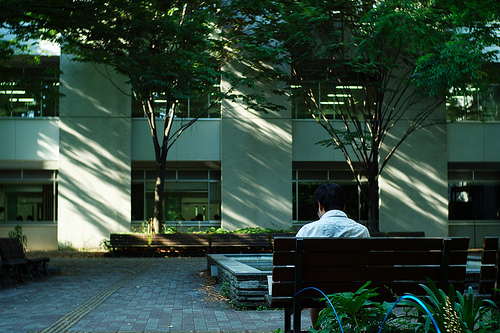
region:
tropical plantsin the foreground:
[314, 282, 498, 332]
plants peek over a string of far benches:
[108, 217, 424, 255]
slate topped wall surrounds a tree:
[203, 244, 267, 307]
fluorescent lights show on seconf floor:
[1, 64, 493, 116]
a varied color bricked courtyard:
[6, 244, 269, 330]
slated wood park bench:
[273, 234, 471, 306]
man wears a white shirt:
[293, 204, 373, 241]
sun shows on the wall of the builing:
[13, 18, 447, 248]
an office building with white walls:
[2, 19, 497, 249]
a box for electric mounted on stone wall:
[198, 255, 227, 284]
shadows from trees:
[55, 48, 129, 188]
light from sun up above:
[44, 151, 134, 210]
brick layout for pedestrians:
[56, 259, 186, 313]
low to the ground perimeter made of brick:
[207, 246, 263, 299]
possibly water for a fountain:
[253, 260, 269, 267]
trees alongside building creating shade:
[59, 6, 238, 227]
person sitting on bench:
[268, 183, 465, 288]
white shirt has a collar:
[298, 210, 373, 237]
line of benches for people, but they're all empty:
[103, 233, 271, 248]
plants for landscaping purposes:
[432, 284, 494, 330]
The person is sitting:
[256, 155, 386, 281]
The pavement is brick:
[102, 278, 182, 328]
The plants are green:
[325, 290, 442, 330]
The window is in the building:
[115, 144, 257, 245]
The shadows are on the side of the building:
[44, 137, 157, 256]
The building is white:
[220, 125, 297, 211]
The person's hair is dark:
[297, 167, 352, 228]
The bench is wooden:
[266, 218, 363, 298]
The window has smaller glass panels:
[278, 137, 411, 235]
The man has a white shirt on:
[299, 214, 384, 248]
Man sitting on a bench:
[290, 188, 368, 234]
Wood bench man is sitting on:
[267, 235, 463, 331]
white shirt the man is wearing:
[292, 207, 369, 235]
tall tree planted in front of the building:
[227, 0, 497, 228]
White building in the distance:
[0, 15, 498, 233]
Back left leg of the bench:
[290, 305, 300, 330]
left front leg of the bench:
[280, 303, 291, 328]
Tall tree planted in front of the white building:
[1, 0, 274, 233]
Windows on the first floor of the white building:
[1, 162, 496, 222]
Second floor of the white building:
[0, 57, 499, 118]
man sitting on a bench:
[220, 150, 486, 324]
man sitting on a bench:
[252, 162, 407, 311]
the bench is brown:
[111, 223, 253, 269]